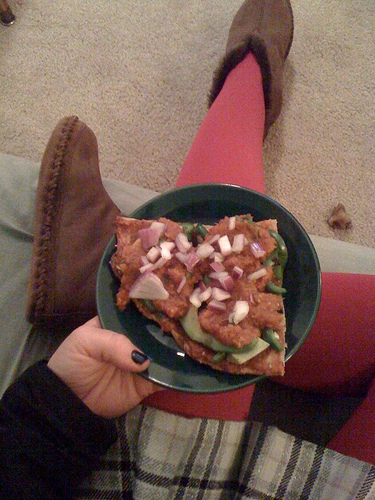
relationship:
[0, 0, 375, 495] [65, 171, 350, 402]
woman holding plate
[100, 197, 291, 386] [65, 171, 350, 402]
food on plate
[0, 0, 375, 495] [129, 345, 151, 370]
woman has finernail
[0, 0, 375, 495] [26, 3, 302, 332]
woman wearing shoes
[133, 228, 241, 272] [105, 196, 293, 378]
onions on pizza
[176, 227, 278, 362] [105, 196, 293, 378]
peppers on pizza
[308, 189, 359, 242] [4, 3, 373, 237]
nose on floor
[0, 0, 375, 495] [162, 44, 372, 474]
woman wearing leggings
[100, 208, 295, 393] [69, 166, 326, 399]
pizza on plate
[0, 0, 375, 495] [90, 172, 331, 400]
woman holding plate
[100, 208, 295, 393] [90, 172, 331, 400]
pizza on plate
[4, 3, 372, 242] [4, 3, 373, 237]
carpet on floor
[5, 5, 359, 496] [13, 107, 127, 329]
woman has foot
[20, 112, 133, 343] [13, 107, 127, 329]
slipper on foot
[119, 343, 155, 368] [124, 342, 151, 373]
polish on finernail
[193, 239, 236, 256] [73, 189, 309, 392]
onions on top of food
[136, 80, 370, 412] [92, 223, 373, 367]
tights on leg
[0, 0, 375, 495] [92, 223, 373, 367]
woman has leg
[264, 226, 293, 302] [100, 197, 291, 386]
peppers on food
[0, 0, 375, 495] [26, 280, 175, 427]
woman has hand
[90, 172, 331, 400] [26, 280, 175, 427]
plate in hand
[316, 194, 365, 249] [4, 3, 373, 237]
item on floor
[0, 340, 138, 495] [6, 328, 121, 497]
sleeve on sweater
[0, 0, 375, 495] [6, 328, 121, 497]
woman wearing sweater